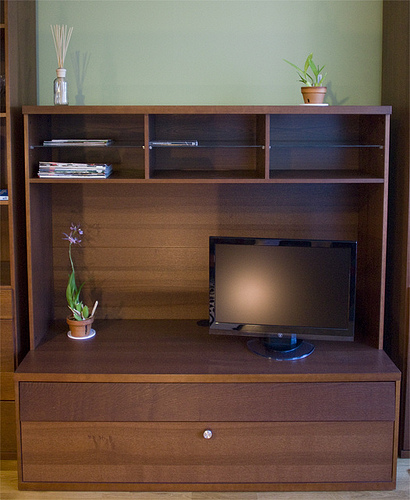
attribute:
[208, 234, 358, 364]
monitor — black, off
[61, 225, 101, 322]
flower — purple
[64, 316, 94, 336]
pot — brown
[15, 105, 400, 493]
desk — wooden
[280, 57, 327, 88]
leaves — green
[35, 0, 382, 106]
wall — green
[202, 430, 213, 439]
knob — silver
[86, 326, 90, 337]
spot — black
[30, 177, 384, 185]
shelf — brown